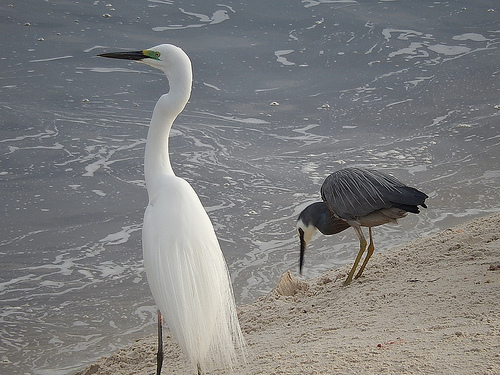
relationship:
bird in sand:
[279, 160, 432, 299] [43, 211, 498, 374]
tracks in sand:
[316, 318, 347, 333] [43, 211, 498, 374]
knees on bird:
[357, 236, 376, 261] [279, 160, 432, 299]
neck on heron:
[134, 84, 188, 184] [80, 32, 256, 375]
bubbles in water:
[269, 97, 283, 109] [2, 3, 498, 375]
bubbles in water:
[101, 10, 114, 21] [2, 3, 498, 375]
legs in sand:
[147, 303, 169, 374] [43, 211, 498, 374]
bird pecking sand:
[279, 160, 432, 299] [43, 211, 498, 374]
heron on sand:
[80, 32, 256, 375] [43, 211, 498, 374]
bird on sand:
[279, 160, 432, 299] [43, 211, 498, 374]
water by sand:
[2, 3, 498, 375] [43, 211, 498, 374]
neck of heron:
[134, 84, 188, 184] [80, 32, 256, 375]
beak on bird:
[296, 238, 310, 275] [279, 160, 432, 299]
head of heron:
[95, 32, 194, 96] [80, 32, 256, 375]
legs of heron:
[147, 303, 169, 374] [80, 32, 256, 375]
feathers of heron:
[166, 286, 253, 373] [80, 32, 256, 375]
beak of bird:
[296, 238, 310, 275] [279, 160, 432, 299]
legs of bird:
[340, 221, 381, 287] [279, 160, 432, 299]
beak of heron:
[93, 47, 151, 66] [80, 32, 256, 375]